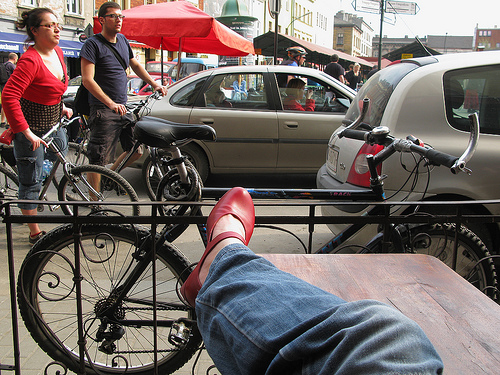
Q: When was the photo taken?
A: During the day.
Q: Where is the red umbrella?
A: Behind the tan car.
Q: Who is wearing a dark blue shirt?
A: The man on the bike.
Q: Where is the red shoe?
A: In the center of the photo.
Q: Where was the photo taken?
A: In a city.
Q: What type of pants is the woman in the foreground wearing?
A: Jeans.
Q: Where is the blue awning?
A: Behind the man and woman on the bikes.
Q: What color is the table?
A: Brown.